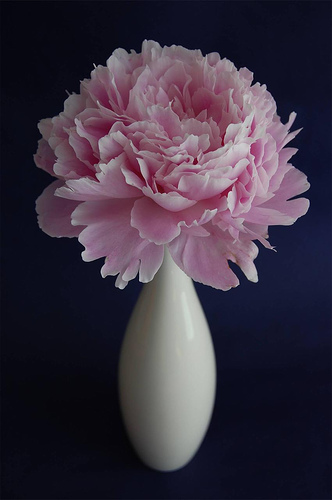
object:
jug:
[119, 245, 217, 472]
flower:
[32, 38, 310, 291]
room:
[1, 2, 330, 499]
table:
[0, 365, 331, 499]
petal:
[129, 197, 218, 247]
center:
[156, 131, 180, 155]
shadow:
[89, 121, 121, 139]